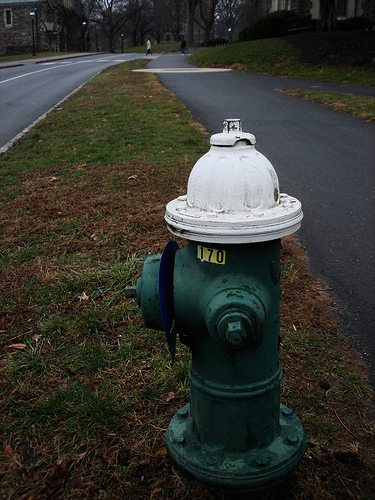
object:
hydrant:
[121, 114, 307, 493]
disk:
[156, 239, 181, 362]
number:
[194, 242, 227, 269]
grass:
[2, 57, 373, 492]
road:
[2, 49, 153, 156]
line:
[0, 50, 132, 85]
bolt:
[223, 319, 250, 348]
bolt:
[220, 114, 243, 137]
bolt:
[121, 280, 140, 303]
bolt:
[280, 401, 297, 420]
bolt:
[282, 430, 301, 446]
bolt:
[176, 405, 190, 419]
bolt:
[169, 431, 187, 445]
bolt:
[202, 454, 223, 469]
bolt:
[252, 451, 271, 470]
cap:
[161, 112, 307, 248]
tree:
[186, 1, 221, 48]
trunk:
[200, 28, 213, 53]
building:
[2, 1, 74, 59]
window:
[4, 8, 16, 29]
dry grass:
[6, 167, 342, 341]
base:
[121, 239, 309, 490]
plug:
[200, 288, 270, 351]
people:
[142, 34, 189, 58]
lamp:
[27, 8, 39, 59]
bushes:
[4, 42, 42, 61]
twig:
[331, 403, 364, 444]